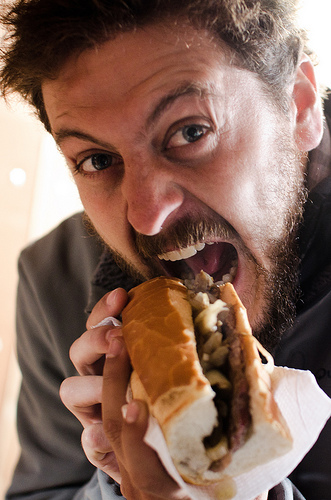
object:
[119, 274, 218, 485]
bread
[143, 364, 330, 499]
paper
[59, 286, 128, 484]
hand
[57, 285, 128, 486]
hands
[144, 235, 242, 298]
mouth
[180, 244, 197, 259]
teeth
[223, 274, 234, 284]
teeth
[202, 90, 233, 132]
wrinkled skin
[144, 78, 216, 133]
eyebrow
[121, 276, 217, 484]
bread roll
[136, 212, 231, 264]
mustache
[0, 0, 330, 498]
guy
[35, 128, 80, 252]
wall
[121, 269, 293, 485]
cheesesteak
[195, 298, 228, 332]
cheese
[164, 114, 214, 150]
blue eyes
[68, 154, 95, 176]
long eyelashes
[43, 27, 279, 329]
man's face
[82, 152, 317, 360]
beard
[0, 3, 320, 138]
hair